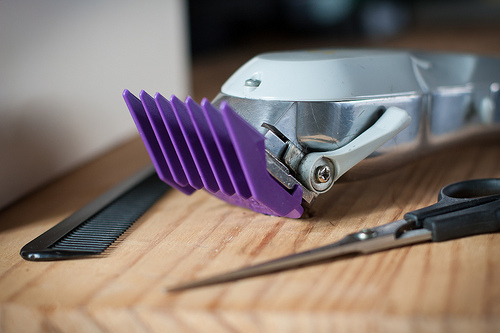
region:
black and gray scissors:
[163, 177, 499, 302]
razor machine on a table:
[121, 38, 497, 225]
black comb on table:
[18, 146, 188, 260]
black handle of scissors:
[405, 177, 495, 242]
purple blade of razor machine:
[123, 91, 307, 217]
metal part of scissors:
[169, 215, 424, 293]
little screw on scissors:
[358, 223, 376, 243]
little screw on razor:
[315, 161, 331, 183]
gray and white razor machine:
[208, 47, 499, 189]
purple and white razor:
[123, 48, 497, 219]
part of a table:
[406, 254, 418, 274]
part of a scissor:
[361, 255, 376, 275]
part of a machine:
[321, 170, 329, 190]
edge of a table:
[296, 188, 310, 211]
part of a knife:
[317, 253, 322, 255]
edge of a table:
[206, 229, 211, 239]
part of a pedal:
[403, 223, 409, 235]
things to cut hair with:
[20, 24, 496, 316]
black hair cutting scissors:
[169, 160, 499, 317]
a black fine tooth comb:
[17, 89, 245, 309]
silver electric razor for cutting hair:
[95, 6, 499, 266]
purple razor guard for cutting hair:
[55, 67, 402, 259]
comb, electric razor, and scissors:
[18, 22, 474, 332]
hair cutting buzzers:
[97, 12, 497, 272]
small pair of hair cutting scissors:
[118, 48, 499, 320]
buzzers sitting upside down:
[66, 24, 499, 251]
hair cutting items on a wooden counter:
[24, 29, 499, 332]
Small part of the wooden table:
[301, 287, 336, 308]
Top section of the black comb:
[21, 230, 101, 257]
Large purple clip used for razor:
[125, 91, 250, 192]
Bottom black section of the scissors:
[410, 175, 495, 230]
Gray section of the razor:
[251, 45, 412, 95]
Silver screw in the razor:
[316, 165, 331, 180]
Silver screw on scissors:
[355, 230, 375, 237]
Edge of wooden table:
[146, 310, 182, 330]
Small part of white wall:
[80, 22, 125, 50]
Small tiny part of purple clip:
[294, 206, 306, 219]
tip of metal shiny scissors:
[154, 254, 237, 297]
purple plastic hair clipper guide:
[120, 79, 307, 223]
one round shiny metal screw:
[313, 157, 334, 185]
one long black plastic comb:
[5, 172, 171, 269]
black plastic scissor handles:
[417, 167, 499, 264]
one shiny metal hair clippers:
[112, 24, 498, 219]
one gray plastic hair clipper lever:
[302, 102, 419, 198]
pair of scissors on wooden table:
[139, 179, 498, 332]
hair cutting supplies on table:
[18, 20, 492, 303]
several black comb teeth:
[84, 216, 115, 254]